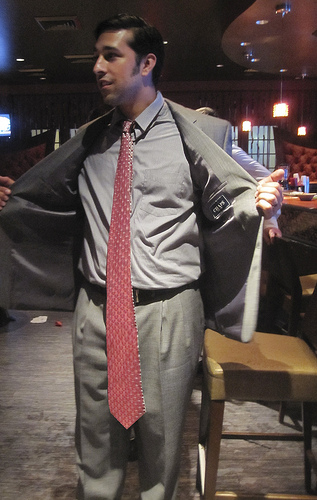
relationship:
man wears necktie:
[56, 15, 219, 499] [104, 117, 153, 431]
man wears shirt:
[56, 15, 219, 499] [65, 92, 205, 297]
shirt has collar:
[65, 92, 205, 297] [93, 90, 170, 140]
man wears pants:
[56, 15, 219, 499] [66, 280, 206, 499]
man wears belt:
[56, 15, 219, 499] [80, 272, 203, 304]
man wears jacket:
[56, 15, 219, 499] [2, 93, 276, 344]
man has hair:
[56, 15, 219, 499] [91, 10, 166, 91]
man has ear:
[56, 15, 219, 499] [141, 51, 158, 80]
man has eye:
[56, 15, 219, 499] [104, 51, 122, 63]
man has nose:
[56, 15, 219, 499] [92, 56, 110, 75]